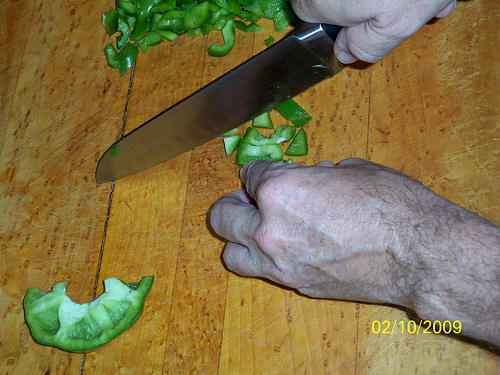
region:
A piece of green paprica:
[288, 123, 309, 157]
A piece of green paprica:
[241, 125, 292, 157]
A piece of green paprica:
[204, 27, 241, 57]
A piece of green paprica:
[71, 35, 156, 86]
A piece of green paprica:
[165, 11, 196, 41]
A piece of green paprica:
[188, 1, 213, 22]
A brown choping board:
[10, 75, 98, 247]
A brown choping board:
[412, 81, 497, 178]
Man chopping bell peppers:
[91, 3, 498, 350]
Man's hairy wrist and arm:
[211, 146, 499, 346]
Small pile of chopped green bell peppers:
[213, 92, 313, 172]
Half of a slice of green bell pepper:
[15, 271, 167, 351]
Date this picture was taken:
[366, 310, 461, 345]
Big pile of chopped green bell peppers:
[90, 0, 310, 77]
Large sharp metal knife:
[83, 15, 362, 189]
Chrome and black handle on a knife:
[285, 15, 366, 81]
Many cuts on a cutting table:
[11, 118, 231, 271]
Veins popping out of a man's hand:
[283, 209, 406, 286]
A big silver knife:
[87, 1, 334, 183]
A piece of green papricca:
[296, 128, 310, 157]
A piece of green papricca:
[279, 92, 316, 126]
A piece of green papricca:
[229, 125, 282, 164]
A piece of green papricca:
[94, 40, 142, 65]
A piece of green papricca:
[207, 18, 237, 57]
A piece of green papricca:
[94, 0, 135, 42]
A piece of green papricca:
[266, 0, 289, 27]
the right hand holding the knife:
[290, 0, 457, 64]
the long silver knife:
[94, 0, 454, 185]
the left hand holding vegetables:
[210, 156, 499, 345]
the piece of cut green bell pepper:
[22, 275, 152, 351]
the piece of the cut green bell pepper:
[284, 127, 307, 156]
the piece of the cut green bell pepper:
[208, 18, 234, 56]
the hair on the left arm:
[351, 175, 498, 350]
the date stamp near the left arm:
[372, 320, 461, 333]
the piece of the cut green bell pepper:
[262, 35, 274, 47]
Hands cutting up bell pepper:
[22, 5, 480, 346]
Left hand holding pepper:
[191, 136, 486, 331]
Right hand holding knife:
[280, 2, 452, 60]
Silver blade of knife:
[56, 54, 351, 182]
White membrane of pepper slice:
[43, 263, 127, 318]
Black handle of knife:
[298, 27, 361, 71]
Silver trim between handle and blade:
[298, 27, 345, 83]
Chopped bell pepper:
[102, 0, 281, 53]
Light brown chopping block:
[365, 80, 454, 138]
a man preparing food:
[22, 6, 444, 368]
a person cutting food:
[26, 11, 482, 357]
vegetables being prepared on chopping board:
[23, 8, 435, 372]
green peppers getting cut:
[31, 13, 416, 346]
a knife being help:
[44, 10, 494, 220]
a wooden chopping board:
[54, 11, 446, 362]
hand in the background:
[156, 82, 498, 359]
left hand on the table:
[238, 153, 425, 278]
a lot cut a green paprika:
[114, 10, 240, 34]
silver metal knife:
[126, 86, 255, 151]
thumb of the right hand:
[332, 50, 352, 65]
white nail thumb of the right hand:
[340, 52, 351, 64]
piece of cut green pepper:
[18, 265, 190, 362]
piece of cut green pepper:
[16, 259, 179, 361]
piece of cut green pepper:
[17, 258, 185, 359]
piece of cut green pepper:
[16, 263, 161, 353]